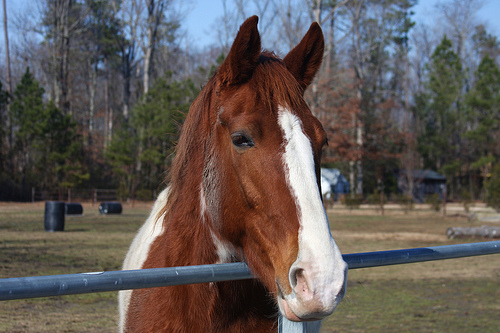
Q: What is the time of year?
A: Fall.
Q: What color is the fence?
A: Blue.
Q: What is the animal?
A: A horse.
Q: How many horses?
A: 1.